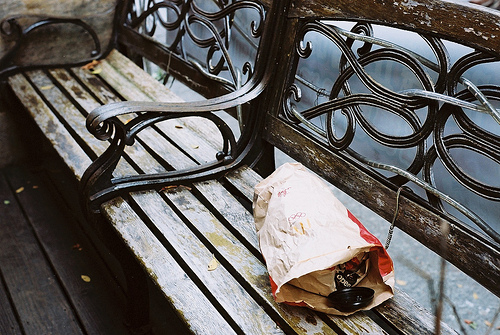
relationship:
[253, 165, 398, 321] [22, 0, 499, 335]
bag laying on top of bench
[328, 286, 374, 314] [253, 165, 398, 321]
lid inside bag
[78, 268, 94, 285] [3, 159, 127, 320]
leaf on ground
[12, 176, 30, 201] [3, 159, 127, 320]
leaf on ground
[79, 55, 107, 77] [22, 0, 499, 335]
leaf on top of bench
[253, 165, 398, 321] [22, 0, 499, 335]
bag on bench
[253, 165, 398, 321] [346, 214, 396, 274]
bag has mcdonalds logo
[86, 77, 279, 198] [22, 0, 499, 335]
arm rest in middle of bench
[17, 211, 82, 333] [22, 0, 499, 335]
boards are in front of bench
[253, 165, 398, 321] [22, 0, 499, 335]
bag sits upon bench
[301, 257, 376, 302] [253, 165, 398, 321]
trash inside bag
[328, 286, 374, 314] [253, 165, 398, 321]
coffee lid inside bag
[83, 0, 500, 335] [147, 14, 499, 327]
bench next to another bench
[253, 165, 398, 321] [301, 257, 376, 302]
paper bag full of fast food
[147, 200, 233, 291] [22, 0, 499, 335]
wooden slats are on bench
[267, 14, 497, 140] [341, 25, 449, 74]
bench back has ironworking cable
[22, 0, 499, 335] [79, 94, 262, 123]
bench has bench handle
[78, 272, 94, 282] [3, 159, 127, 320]
leaf litter floor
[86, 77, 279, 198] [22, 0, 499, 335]
arm rest on top of bench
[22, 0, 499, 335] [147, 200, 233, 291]
bench has wooden slats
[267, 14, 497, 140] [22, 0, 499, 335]
bench back behind bench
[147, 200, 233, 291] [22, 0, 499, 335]
wooden slats form bench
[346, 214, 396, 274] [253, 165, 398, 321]
mcdonalds logo on side of bag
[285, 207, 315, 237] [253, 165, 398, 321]
olympics logo on bag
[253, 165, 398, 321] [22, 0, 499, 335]
bag lying on top of bench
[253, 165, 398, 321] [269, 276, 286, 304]
bag has trim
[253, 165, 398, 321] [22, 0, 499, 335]
bag on top of bench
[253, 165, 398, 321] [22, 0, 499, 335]
paper sack on top of bench